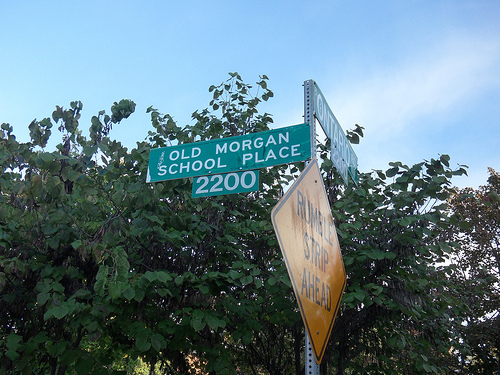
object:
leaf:
[41, 174, 62, 194]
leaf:
[122, 182, 145, 194]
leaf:
[133, 186, 154, 209]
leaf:
[154, 269, 169, 285]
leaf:
[142, 268, 159, 283]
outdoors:
[0, 0, 498, 374]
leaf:
[115, 97, 132, 111]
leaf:
[393, 190, 416, 203]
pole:
[300, 78, 318, 374]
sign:
[142, 121, 312, 186]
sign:
[312, 83, 358, 187]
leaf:
[383, 165, 402, 178]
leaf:
[49, 302, 71, 319]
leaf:
[239, 273, 253, 287]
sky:
[0, 1, 499, 327]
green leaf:
[438, 154, 451, 170]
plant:
[0, 70, 499, 375]